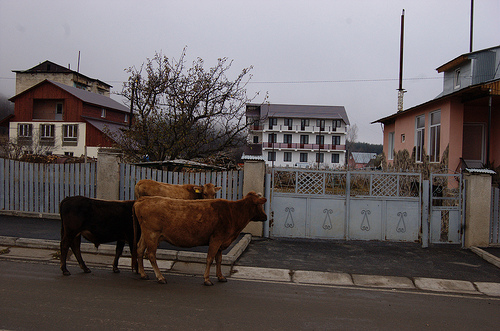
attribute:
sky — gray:
[168, 14, 375, 79]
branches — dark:
[101, 43, 273, 167]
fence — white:
[1, 157, 467, 249]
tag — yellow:
[189, 185, 219, 196]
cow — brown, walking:
[131, 175, 218, 200]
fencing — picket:
[1, 152, 465, 248]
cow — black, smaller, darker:
[58, 180, 267, 277]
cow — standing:
[53, 192, 143, 279]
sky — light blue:
[2, 0, 499, 147]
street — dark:
[1, 245, 498, 327]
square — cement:
[293, 270, 351, 287]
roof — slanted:
[4, 54, 159, 154]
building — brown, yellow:
[9, 56, 156, 163]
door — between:
[414, 154, 477, 256]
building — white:
[246, 102, 349, 181]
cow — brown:
[127, 191, 272, 285]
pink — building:
[394, 117, 411, 134]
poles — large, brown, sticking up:
[368, 15, 448, 153]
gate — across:
[178, 133, 498, 270]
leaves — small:
[143, 62, 168, 92]